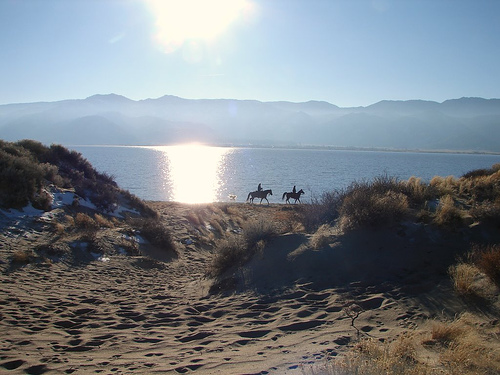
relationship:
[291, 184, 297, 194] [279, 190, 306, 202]
person riding horse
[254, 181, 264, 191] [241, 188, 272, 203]
person riding horse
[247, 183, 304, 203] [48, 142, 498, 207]
riders on water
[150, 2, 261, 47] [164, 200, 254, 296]
sun reflecting on ground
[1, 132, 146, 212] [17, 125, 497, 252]
bushes on shore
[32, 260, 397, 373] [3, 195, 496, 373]
sand filling ground